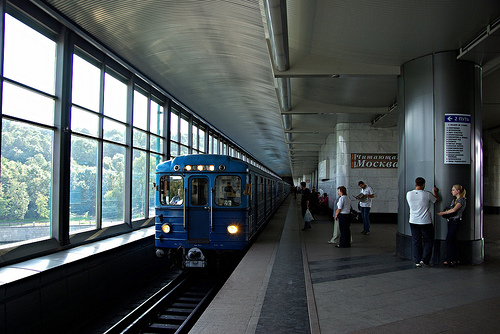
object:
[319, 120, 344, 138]
ground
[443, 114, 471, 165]
wall sign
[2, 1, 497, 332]
area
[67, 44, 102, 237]
window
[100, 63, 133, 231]
window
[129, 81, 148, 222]
window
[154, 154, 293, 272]
train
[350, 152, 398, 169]
sign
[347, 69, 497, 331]
hallway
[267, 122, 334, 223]
hallway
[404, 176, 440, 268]
man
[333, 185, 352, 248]
people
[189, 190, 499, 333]
platform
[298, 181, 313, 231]
man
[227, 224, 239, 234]
light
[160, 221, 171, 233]
light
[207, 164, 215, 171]
light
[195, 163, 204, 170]
light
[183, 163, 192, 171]
light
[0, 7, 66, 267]
window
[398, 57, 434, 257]
wall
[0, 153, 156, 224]
bushes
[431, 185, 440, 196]
hand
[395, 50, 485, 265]
pillar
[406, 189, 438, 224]
shirt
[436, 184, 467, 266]
lady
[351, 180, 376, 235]
man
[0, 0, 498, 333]
train station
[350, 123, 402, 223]
wall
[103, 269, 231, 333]
tracks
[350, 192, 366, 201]
object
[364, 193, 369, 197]
hands